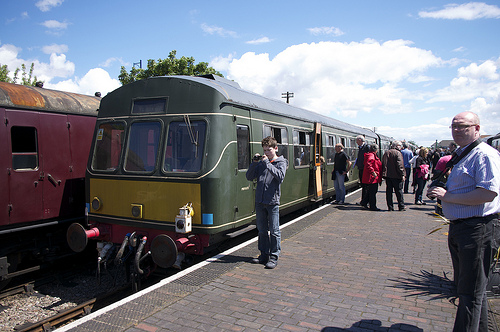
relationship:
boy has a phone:
[246, 138, 288, 270] [251, 153, 264, 162]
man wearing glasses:
[431, 113, 499, 331] [450, 122, 478, 130]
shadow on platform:
[387, 269, 454, 304] [291, 206, 444, 331]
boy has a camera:
[246, 138, 288, 270] [251, 153, 264, 162]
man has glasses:
[431, 113, 499, 331] [450, 122, 478, 130]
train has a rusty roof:
[1, 82, 86, 288] [1, 84, 98, 115]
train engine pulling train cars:
[85, 72, 247, 265] [378, 133, 393, 168]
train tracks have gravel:
[0, 278, 117, 331] [0, 286, 26, 332]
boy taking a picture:
[246, 138, 288, 270] [251, 153, 264, 162]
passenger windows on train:
[294, 127, 313, 167] [85, 72, 247, 265]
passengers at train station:
[332, 135, 363, 209] [0, 1, 499, 331]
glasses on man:
[450, 122, 478, 130] [431, 113, 499, 331]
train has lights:
[85, 72, 247, 265] [90, 195, 103, 211]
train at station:
[85, 72, 247, 265] [0, 1, 499, 331]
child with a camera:
[246, 138, 288, 270] [251, 153, 264, 162]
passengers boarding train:
[332, 135, 363, 209] [85, 72, 247, 265]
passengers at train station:
[331, 142, 352, 204] [0, 1, 499, 331]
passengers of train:
[332, 135, 363, 209] [85, 72, 247, 265]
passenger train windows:
[331, 142, 352, 204] [291, 128, 312, 167]